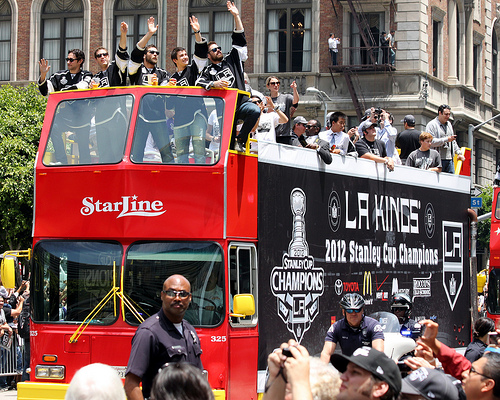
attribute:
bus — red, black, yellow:
[33, 93, 471, 256]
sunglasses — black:
[66, 55, 78, 64]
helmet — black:
[340, 291, 369, 311]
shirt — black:
[133, 322, 207, 358]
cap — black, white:
[330, 347, 395, 368]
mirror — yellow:
[233, 294, 256, 319]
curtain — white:
[66, 21, 81, 36]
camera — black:
[376, 109, 384, 116]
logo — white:
[78, 194, 172, 224]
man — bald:
[157, 272, 192, 330]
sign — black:
[261, 189, 475, 298]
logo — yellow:
[362, 269, 374, 295]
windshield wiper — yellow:
[63, 263, 117, 344]